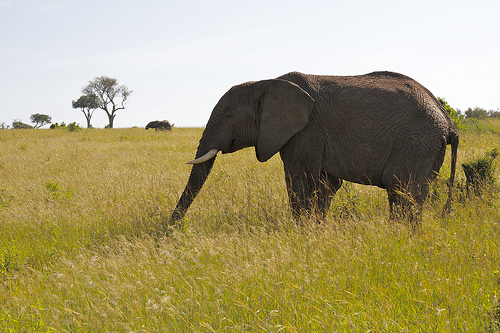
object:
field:
[310, 70, 427, 267]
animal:
[146, 121, 169, 129]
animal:
[168, 70, 458, 234]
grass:
[447, 203, 488, 330]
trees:
[82, 77, 133, 129]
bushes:
[1, 122, 87, 132]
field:
[16, 121, 63, 285]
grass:
[2, 121, 19, 328]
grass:
[35, 206, 55, 302]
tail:
[441, 133, 459, 219]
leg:
[283, 155, 325, 224]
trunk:
[168, 131, 219, 226]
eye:
[224, 114, 230, 119]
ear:
[256, 79, 316, 162]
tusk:
[182, 148, 219, 165]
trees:
[72, 95, 105, 128]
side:
[72, 75, 133, 129]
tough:
[314, 93, 420, 164]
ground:
[219, 244, 270, 333]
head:
[168, 80, 315, 225]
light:
[6, 70, 190, 168]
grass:
[345, 185, 387, 219]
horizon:
[12, 70, 183, 222]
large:
[255, 78, 316, 162]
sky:
[3, 53, 498, 133]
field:
[11, 283, 497, 330]